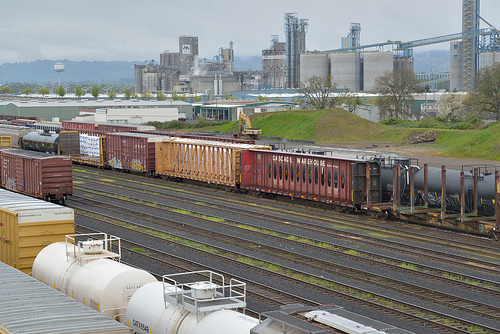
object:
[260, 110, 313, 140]
grass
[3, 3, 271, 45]
sky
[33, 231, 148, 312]
tank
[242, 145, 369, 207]
carrier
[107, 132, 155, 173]
container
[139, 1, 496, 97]
plant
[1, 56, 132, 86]
mountain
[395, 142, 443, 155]
soil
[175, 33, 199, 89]
building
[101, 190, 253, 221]
tracks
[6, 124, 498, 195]
train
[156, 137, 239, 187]
car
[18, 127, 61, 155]
tank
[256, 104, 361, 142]
hill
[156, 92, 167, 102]
tree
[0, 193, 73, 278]
car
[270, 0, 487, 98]
refinery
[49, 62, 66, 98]
tower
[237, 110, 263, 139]
backhoe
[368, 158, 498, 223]
car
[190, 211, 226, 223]
grass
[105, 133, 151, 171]
car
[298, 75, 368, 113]
trees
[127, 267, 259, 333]
tanker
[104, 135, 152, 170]
cars